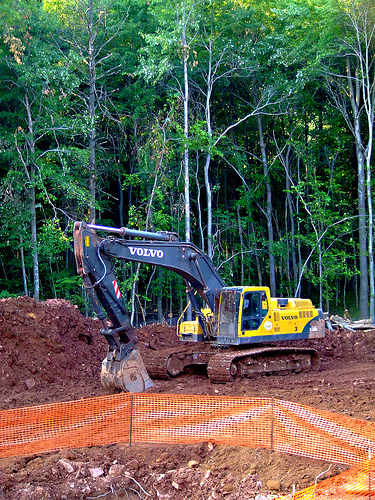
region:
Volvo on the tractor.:
[121, 236, 177, 266]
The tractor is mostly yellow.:
[202, 270, 331, 345]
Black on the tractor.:
[77, 223, 187, 359]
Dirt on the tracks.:
[152, 339, 302, 403]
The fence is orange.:
[27, 398, 373, 498]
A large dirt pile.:
[13, 298, 123, 378]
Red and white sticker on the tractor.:
[106, 274, 128, 304]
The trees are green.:
[2, 56, 123, 279]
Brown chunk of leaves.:
[0, 24, 28, 67]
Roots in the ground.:
[67, 463, 156, 498]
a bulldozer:
[130, 218, 308, 429]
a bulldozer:
[186, 274, 318, 482]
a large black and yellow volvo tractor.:
[61, 197, 328, 387]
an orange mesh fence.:
[0, 376, 374, 479]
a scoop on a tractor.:
[93, 345, 157, 399]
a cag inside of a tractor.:
[214, 281, 268, 344]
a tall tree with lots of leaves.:
[178, 0, 193, 330]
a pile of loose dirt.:
[0, 287, 369, 380]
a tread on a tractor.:
[189, 338, 329, 391]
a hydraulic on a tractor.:
[71, 225, 181, 236]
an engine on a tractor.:
[273, 289, 319, 322]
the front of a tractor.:
[172, 289, 223, 354]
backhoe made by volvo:
[59, 211, 357, 390]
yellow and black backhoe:
[55, 206, 340, 397]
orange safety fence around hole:
[6, 392, 366, 494]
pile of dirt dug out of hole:
[5, 283, 147, 406]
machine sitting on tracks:
[149, 342, 332, 382]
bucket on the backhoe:
[88, 338, 169, 401]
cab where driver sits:
[219, 280, 273, 341]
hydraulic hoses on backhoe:
[71, 230, 180, 298]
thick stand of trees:
[7, 108, 349, 301]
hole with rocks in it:
[27, 446, 310, 497]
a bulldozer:
[59, 170, 279, 399]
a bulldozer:
[64, 191, 360, 498]